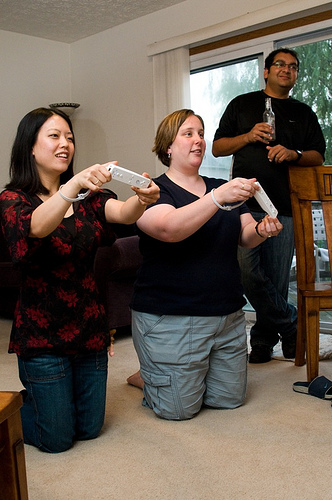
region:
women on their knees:
[34, 61, 331, 453]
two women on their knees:
[4, 77, 263, 488]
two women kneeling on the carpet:
[1, 90, 306, 446]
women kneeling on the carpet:
[34, 85, 311, 466]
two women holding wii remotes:
[31, 58, 310, 410]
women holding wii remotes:
[6, 86, 282, 284]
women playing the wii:
[9, 87, 298, 279]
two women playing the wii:
[23, 90, 331, 309]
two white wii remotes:
[70, 152, 290, 229]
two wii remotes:
[10, 126, 285, 256]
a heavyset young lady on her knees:
[114, 105, 276, 418]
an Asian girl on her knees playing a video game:
[2, 101, 129, 460]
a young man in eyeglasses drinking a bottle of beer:
[213, 39, 319, 358]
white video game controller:
[88, 158, 155, 204]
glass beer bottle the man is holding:
[258, 97, 278, 142]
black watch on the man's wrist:
[290, 147, 304, 164]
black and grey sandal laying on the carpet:
[287, 371, 331, 404]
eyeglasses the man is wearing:
[272, 58, 299, 73]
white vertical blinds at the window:
[150, 49, 196, 113]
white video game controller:
[240, 174, 279, 220]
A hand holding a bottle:
[254, 94, 279, 149]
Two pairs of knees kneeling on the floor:
[19, 348, 254, 457]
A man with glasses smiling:
[258, 43, 306, 97]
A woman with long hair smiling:
[5, 100, 77, 181]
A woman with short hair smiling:
[149, 105, 213, 175]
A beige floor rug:
[130, 437, 282, 489]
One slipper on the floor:
[288, 370, 331, 403]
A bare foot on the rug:
[124, 364, 149, 392]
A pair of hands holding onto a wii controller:
[198, 164, 295, 242]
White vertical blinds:
[146, 49, 198, 108]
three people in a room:
[8, 34, 330, 492]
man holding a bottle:
[212, 44, 330, 374]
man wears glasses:
[217, 38, 325, 146]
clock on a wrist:
[264, 138, 315, 168]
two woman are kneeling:
[0, 96, 276, 454]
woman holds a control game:
[2, 98, 156, 461]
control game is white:
[55, 158, 159, 205]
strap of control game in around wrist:
[49, 158, 150, 211]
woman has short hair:
[127, 99, 235, 206]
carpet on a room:
[5, 320, 324, 498]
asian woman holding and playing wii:
[4, 104, 163, 454]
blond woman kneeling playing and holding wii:
[124, 108, 290, 420]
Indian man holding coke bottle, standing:
[210, 44, 322, 367]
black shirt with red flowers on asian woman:
[2, 173, 120, 352]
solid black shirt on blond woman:
[128, 169, 254, 314]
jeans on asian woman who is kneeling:
[21, 340, 112, 458]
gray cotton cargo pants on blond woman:
[125, 299, 248, 421]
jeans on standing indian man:
[238, 203, 307, 356]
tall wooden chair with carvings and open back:
[285, 160, 329, 385]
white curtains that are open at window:
[148, 47, 195, 189]